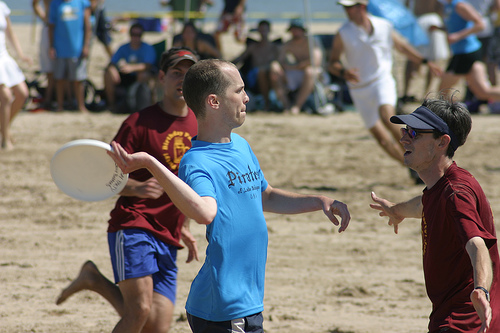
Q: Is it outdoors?
A: Yes, it is outdoors.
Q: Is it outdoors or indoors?
A: It is outdoors.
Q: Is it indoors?
A: No, it is outdoors.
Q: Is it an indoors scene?
A: No, it is outdoors.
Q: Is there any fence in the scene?
A: No, there are no fences.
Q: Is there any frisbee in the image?
A: Yes, there is a frisbee.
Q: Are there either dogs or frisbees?
A: Yes, there is a frisbee.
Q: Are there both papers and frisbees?
A: No, there is a frisbee but no papers.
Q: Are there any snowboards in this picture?
A: No, there are no snowboards.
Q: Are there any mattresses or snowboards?
A: No, there are no snowboards or mattresses.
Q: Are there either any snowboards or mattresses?
A: No, there are no snowboards or mattresses.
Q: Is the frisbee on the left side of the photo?
A: Yes, the frisbee is on the left of the image.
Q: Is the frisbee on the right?
A: No, the frisbee is on the left of the image.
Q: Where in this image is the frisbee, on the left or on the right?
A: The frisbee is on the left of the image.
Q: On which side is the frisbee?
A: The frisbee is on the left of the image.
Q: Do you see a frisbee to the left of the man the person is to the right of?
A: Yes, there is a frisbee to the left of the man.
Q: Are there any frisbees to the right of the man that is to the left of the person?
A: No, the frisbee is to the left of the man.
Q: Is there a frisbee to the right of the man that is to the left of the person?
A: No, the frisbee is to the left of the man.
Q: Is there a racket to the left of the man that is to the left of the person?
A: No, there is a frisbee to the left of the man.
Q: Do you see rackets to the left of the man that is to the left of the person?
A: No, there is a frisbee to the left of the man.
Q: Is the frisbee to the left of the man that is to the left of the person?
A: Yes, the frisbee is to the left of the man.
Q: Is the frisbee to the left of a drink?
A: No, the frisbee is to the left of the man.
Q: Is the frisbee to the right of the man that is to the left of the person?
A: No, the frisbee is to the left of the man.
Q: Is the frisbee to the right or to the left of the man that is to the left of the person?
A: The frisbee is to the left of the man.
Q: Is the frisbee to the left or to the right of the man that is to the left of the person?
A: The frisbee is to the left of the man.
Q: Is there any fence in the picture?
A: No, there are no fences.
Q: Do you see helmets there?
A: No, there are no helmets.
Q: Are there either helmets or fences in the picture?
A: No, there are no helmets or fences.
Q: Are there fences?
A: No, there are no fences.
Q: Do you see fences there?
A: No, there are no fences.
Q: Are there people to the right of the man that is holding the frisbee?
A: Yes, there is a person to the right of the man.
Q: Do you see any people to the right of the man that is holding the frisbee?
A: Yes, there is a person to the right of the man.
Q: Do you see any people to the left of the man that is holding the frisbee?
A: No, the person is to the right of the man.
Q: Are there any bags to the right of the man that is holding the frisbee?
A: No, there is a person to the right of the man.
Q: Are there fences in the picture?
A: No, there are no fences.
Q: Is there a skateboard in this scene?
A: No, there are no skateboards.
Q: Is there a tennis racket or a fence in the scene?
A: No, there are no fences or rackets.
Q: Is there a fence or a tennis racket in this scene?
A: No, there are no fences or rackets.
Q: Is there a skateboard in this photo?
A: No, there are no skateboards.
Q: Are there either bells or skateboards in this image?
A: No, there are no skateboards or bells.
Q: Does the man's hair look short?
A: Yes, the hair is short.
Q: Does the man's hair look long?
A: No, the hair is short.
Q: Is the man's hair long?
A: No, the hair is short.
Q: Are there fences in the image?
A: No, there are no fences.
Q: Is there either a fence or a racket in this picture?
A: No, there are no fences or rackets.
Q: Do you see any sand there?
A: Yes, there is sand.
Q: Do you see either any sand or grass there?
A: Yes, there is sand.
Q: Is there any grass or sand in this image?
A: Yes, there is sand.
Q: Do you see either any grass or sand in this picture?
A: Yes, there is sand.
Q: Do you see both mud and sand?
A: No, there is sand but no mud.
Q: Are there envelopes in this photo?
A: No, there are no envelopes.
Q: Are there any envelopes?
A: No, there are no envelopes.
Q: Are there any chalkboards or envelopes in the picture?
A: No, there are no envelopes or chalkboards.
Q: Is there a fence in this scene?
A: No, there are no fences.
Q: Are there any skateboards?
A: No, there are no skateboards.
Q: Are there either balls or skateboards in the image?
A: No, there are no skateboards or balls.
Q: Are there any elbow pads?
A: No, there are no elbow pads.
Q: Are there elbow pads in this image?
A: No, there are no elbow pads.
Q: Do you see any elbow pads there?
A: No, there are no elbow pads.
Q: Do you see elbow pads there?
A: No, there are no elbow pads.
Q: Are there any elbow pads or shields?
A: No, there are no elbow pads or shields.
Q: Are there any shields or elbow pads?
A: No, there are no elbow pads or shields.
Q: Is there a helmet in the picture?
A: No, there are no helmets.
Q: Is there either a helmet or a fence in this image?
A: No, there are no helmets or fences.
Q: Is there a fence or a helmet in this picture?
A: No, there are no helmets or fences.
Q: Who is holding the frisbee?
A: The man is holding the frisbee.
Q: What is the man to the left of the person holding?
A: The man is holding the frisbee.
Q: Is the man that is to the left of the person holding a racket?
A: No, the man is holding the frisbee.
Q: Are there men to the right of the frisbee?
A: Yes, there is a man to the right of the frisbee.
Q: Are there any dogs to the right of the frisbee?
A: No, there is a man to the right of the frisbee.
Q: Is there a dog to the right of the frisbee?
A: No, there is a man to the right of the frisbee.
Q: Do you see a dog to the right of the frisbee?
A: No, there is a man to the right of the frisbee.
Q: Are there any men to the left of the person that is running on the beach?
A: Yes, there is a man to the left of the person.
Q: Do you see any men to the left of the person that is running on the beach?
A: Yes, there is a man to the left of the person.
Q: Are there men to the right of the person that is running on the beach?
A: No, the man is to the left of the person.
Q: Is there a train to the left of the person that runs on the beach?
A: No, there is a man to the left of the person.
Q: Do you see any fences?
A: No, there are no fences.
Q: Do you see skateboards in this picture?
A: No, there are no skateboards.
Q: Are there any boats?
A: No, there are no boats.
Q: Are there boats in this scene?
A: No, there are no boats.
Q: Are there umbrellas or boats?
A: No, there are no boats or umbrellas.